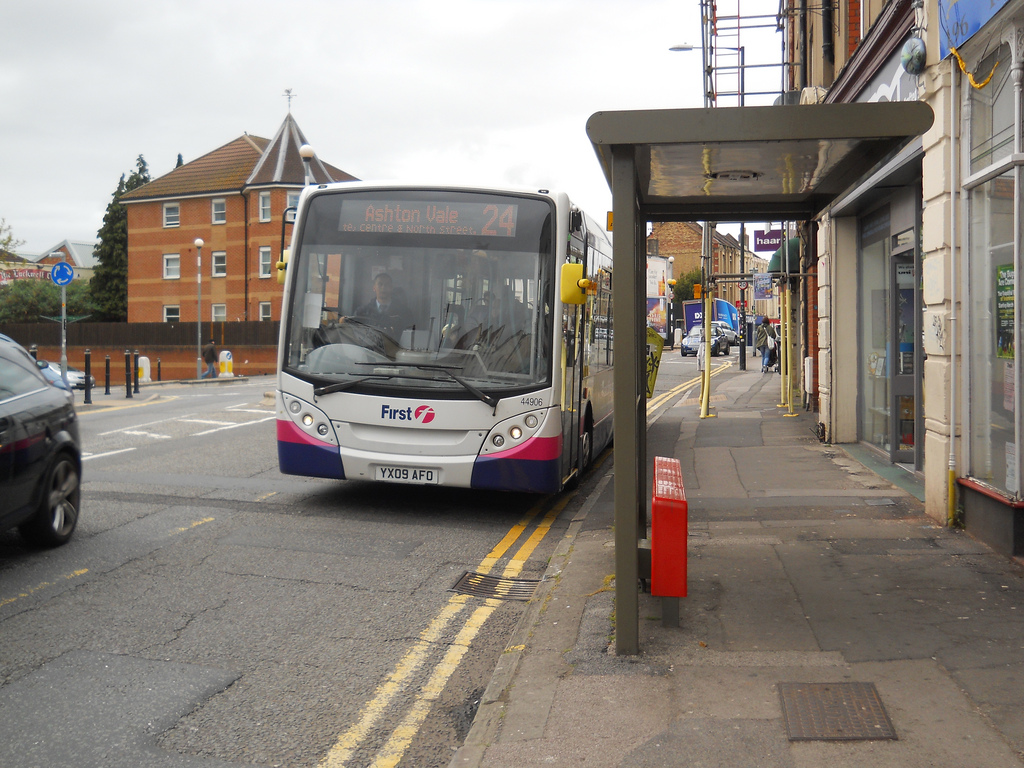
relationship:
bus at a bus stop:
[274, 177, 614, 496] [584, 98, 939, 688]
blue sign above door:
[935, 0, 1021, 84] [954, 177, 1022, 528]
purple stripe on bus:
[270, 441, 553, 486] [273, 177, 638, 485]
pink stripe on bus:
[272, 415, 555, 460] [273, 177, 638, 485]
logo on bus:
[373, 390, 441, 425] [275, 180, 612, 491]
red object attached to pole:
[646, 452, 700, 615] [630, 538, 659, 592]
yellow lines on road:
[257, 355, 744, 766] [0, 313, 729, 765]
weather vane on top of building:
[272, 77, 311, 120] [123, 112, 364, 401]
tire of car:
[29, 447, 100, 549] [0, 335, 122, 552]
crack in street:
[1, 632, 97, 686] [0, 333, 738, 763]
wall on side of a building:
[121, 208, 160, 321] [124, 134, 368, 340]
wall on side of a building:
[121, 208, 160, 322] [107, 123, 341, 321]